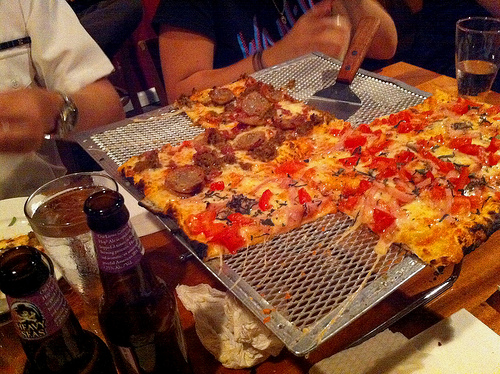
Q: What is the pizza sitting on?
A: A tray.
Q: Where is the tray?
A: On the table.